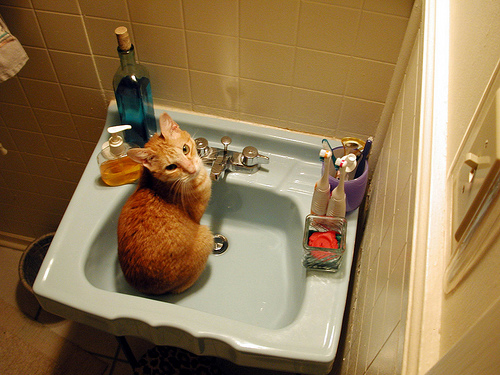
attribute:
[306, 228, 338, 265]
candle — red 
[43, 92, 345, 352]
sink — White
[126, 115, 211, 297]
tabby cat — blonde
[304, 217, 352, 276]
candle — red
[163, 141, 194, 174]
eyes — green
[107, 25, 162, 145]
bottle — decorative, tinted blue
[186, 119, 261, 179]
faucet — silver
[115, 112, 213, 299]
cat — light orange, tabby cat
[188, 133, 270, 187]
faucet — silver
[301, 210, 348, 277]
candle holder — clear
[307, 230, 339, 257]
candle — red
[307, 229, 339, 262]
candle — red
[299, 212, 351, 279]
holder — square shaped, thick glass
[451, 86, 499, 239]
light switch — cream colored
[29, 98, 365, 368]
sink — light blue, pale blue